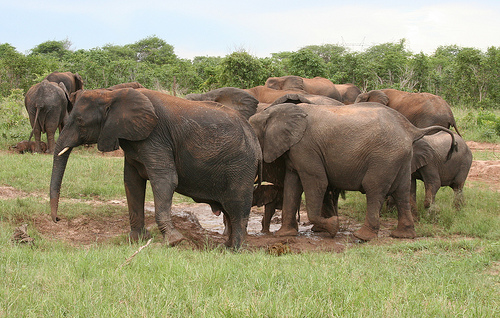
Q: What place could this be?
A: It is a field.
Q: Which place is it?
A: It is a field.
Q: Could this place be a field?
A: Yes, it is a field.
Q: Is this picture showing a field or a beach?
A: It is showing a field.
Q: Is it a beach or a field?
A: It is a field.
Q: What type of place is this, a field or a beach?
A: It is a field.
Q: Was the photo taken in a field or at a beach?
A: It was taken at a field.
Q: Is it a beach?
A: No, it is a field.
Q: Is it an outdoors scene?
A: Yes, it is outdoors.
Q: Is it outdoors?
A: Yes, it is outdoors.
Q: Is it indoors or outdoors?
A: It is outdoors.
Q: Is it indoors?
A: No, it is outdoors.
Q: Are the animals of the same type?
A: Yes, all the animals are elephants.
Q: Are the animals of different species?
A: No, all the animals are elephants.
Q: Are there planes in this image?
A: No, there are no planes.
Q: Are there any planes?
A: No, there are no planes.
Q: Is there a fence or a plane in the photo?
A: No, there are no airplanes or fences.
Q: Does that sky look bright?
A: Yes, the sky is bright.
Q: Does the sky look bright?
A: Yes, the sky is bright.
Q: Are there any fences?
A: No, there are no fences.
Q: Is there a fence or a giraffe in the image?
A: No, there are no fences or giraffes.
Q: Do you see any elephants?
A: Yes, there are elephants.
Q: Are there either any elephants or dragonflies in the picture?
A: Yes, there are elephants.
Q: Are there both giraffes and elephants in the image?
A: No, there are elephants but no giraffes.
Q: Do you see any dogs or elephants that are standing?
A: Yes, the elephants are standing.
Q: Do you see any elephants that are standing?
A: Yes, there are elephants that are standing.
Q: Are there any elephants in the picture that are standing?
A: Yes, there are elephants that are standing.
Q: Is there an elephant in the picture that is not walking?
A: Yes, there are elephants that are standing.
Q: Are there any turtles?
A: No, there are no turtles.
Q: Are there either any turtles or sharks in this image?
A: No, there are no turtles or sharks.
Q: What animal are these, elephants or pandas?
A: These are elephants.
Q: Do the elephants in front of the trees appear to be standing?
A: Yes, the elephants are standing.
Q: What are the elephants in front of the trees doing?
A: The elephants are standing.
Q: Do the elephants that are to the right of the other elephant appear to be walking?
A: No, the elephants are standing.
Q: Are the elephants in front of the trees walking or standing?
A: The elephants are standing.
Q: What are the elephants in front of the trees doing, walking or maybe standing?
A: The elephants are standing.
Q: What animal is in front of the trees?
A: The elephants are in front of the trees.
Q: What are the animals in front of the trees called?
A: The animals are elephants.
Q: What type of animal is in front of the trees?
A: The animals are elephants.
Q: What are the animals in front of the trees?
A: The animals are elephants.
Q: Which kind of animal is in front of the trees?
A: The animals are elephants.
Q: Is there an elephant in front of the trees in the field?
A: Yes, there are elephants in front of the trees.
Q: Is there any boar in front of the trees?
A: No, there are elephants in front of the trees.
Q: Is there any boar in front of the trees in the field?
A: No, there are elephants in front of the trees.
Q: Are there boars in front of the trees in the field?
A: No, there are elephants in front of the trees.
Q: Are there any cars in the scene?
A: No, there are no cars.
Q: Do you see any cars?
A: No, there are no cars.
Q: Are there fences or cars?
A: No, there are no cars or fences.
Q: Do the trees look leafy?
A: Yes, the trees are leafy.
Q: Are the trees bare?
A: No, the trees are leafy.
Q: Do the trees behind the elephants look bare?
A: No, the trees are leafy.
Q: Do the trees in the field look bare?
A: No, the trees are leafy.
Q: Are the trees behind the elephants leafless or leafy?
A: The trees are leafy.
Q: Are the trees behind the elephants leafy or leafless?
A: The trees are leafy.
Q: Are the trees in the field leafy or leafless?
A: The trees are leafy.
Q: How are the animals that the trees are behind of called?
A: The animals are elephants.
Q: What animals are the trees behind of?
A: The trees are behind the elephants.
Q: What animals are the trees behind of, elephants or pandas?
A: The trees are behind elephants.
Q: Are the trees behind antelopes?
A: No, the trees are behind the elephants.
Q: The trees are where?
A: The trees are in the field.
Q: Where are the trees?
A: The trees are in the field.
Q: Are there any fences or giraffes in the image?
A: No, there are no fences or giraffes.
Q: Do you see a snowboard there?
A: No, there are no snowboards.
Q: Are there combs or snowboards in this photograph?
A: No, there are no snowboards or combs.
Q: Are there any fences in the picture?
A: No, there are no fences.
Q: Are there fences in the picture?
A: No, there are no fences.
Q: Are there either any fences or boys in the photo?
A: No, there are no fences or boys.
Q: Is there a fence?
A: No, there are no fences.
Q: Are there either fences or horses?
A: No, there are no fences or horses.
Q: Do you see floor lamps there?
A: No, there are no floor lamps.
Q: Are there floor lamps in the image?
A: No, there are no floor lamps.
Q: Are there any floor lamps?
A: No, there are no floor lamps.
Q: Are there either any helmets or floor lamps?
A: No, there are no floor lamps or helmets.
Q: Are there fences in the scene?
A: No, there are no fences.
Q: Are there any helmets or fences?
A: No, there are no fences or helmets.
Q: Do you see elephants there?
A: Yes, there is an elephant.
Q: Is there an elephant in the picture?
A: Yes, there is an elephant.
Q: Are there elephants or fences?
A: Yes, there is an elephant.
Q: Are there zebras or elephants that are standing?
A: Yes, the elephant is standing.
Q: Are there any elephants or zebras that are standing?
A: Yes, the elephant is standing.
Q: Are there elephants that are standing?
A: Yes, there is an elephant that is standing.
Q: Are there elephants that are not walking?
A: Yes, there is an elephant that is standing.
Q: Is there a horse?
A: No, there are no horses.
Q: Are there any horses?
A: No, there are no horses.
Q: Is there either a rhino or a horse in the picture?
A: No, there are no horses or rhinos.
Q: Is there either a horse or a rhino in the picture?
A: No, there are no horses or rhinos.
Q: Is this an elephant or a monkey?
A: This is an elephant.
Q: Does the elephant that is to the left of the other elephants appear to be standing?
A: Yes, the elephant is standing.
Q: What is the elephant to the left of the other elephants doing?
A: The elephant is standing.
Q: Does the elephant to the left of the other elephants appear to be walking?
A: No, the elephant is standing.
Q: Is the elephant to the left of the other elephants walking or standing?
A: The elephant is standing.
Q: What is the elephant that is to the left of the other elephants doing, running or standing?
A: The elephant is standing.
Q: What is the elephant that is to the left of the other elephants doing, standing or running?
A: The elephant is standing.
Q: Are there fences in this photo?
A: No, there are no fences.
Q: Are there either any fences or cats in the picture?
A: No, there are no fences or cats.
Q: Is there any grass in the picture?
A: Yes, there is grass.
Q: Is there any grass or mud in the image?
A: Yes, there is grass.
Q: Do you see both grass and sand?
A: No, there is grass but no sand.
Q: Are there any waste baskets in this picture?
A: No, there are no waste baskets.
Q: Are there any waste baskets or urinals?
A: No, there are no waste baskets or urinals.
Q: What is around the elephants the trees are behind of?
A: The grass is around the elephants.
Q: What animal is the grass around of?
A: The grass is around the elephants.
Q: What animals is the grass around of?
A: The grass is around the elephants.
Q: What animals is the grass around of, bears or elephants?
A: The grass is around elephants.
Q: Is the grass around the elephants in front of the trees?
A: Yes, the grass is around the elephants.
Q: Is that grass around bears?
A: No, the grass is around the elephants.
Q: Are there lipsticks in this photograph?
A: No, there are no lipsticks.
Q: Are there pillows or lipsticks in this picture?
A: No, there are no lipsticks or pillows.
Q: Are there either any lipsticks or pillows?
A: No, there are no lipsticks or pillows.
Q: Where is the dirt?
A: The dirt is in the field.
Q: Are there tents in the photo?
A: No, there are no tents.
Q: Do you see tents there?
A: No, there are no tents.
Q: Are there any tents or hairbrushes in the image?
A: No, there are no tents or hairbrushes.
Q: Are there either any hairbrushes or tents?
A: No, there are no tents or hairbrushes.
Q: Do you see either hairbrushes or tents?
A: No, there are no tents or hairbrushes.